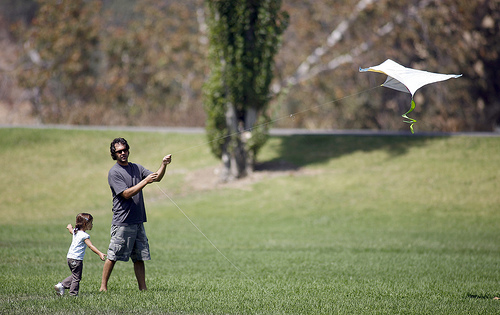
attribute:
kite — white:
[358, 58, 462, 134]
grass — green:
[309, 213, 374, 247]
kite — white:
[332, 22, 492, 127]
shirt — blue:
[110, 140, 135, 222]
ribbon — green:
[403, 100, 417, 132]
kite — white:
[360, 58, 462, 95]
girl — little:
[54, 214, 106, 294]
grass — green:
[351, 214, 478, 276]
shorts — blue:
[103, 216, 152, 261]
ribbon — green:
[394, 96, 420, 133]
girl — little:
[52, 206, 104, 296]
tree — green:
[179, 13, 301, 211]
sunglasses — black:
[113, 144, 130, 152]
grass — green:
[2, 130, 498, 312]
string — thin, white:
[169, 75, 363, 164]